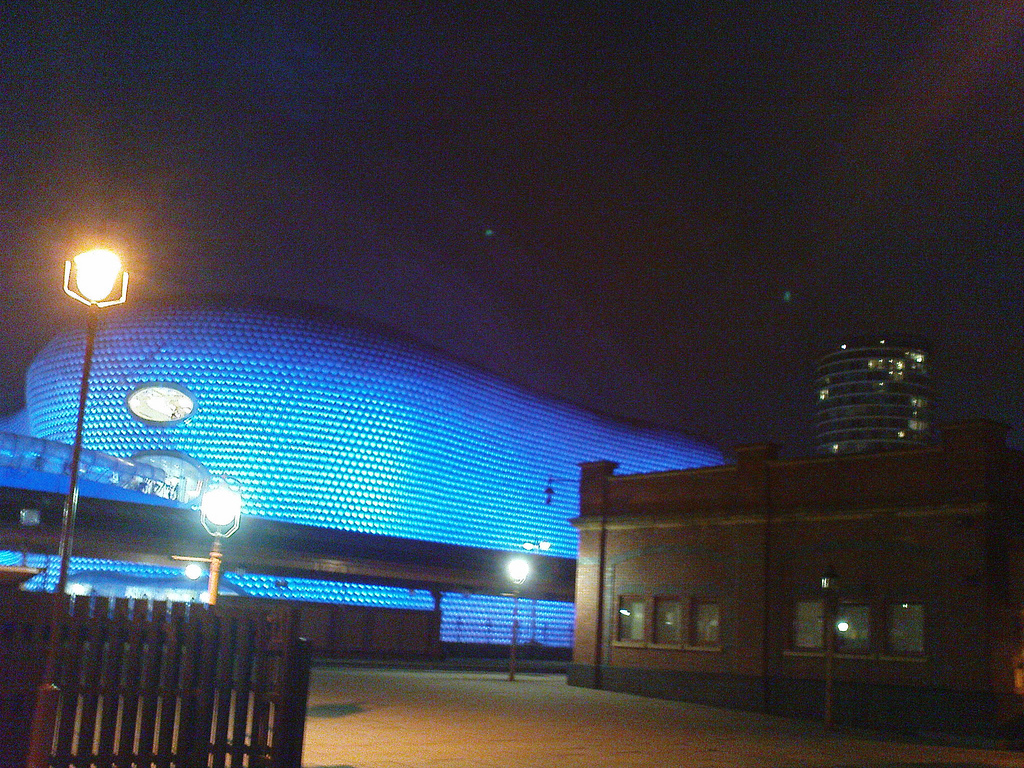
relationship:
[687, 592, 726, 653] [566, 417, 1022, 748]
window on building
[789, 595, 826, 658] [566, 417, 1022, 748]
window on building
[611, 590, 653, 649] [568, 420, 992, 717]
window on building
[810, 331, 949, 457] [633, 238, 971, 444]
building in city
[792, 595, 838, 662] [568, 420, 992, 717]
window on building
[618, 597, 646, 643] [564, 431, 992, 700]
window on building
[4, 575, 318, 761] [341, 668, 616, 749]
fence on sidewalk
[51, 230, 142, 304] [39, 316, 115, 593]
light on pole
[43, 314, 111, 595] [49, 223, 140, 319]
pole on light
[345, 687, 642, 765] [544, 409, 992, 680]
pavement around buildings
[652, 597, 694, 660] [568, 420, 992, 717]
window on building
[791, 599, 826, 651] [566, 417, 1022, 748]
window on building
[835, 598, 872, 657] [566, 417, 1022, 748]
window on building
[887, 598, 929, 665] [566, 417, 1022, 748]
window on building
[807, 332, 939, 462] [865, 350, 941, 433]
building with lights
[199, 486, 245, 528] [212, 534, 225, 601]
light on post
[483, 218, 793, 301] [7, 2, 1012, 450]
stars in sky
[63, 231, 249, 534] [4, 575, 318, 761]
lights behind fence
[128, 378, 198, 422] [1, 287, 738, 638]
light on building